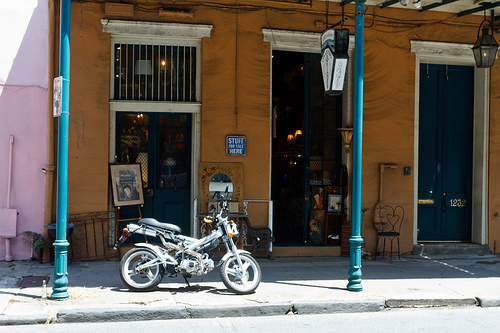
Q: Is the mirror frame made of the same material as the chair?
A: No, the frame is made of wood and the chair is made of metal.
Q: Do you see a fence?
A: No, there are no fences.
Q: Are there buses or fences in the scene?
A: No, there are no fences or buses.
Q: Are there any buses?
A: No, there are no buses.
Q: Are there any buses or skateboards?
A: No, there are no buses or skateboards.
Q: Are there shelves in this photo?
A: No, there are no shelves.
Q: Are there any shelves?
A: No, there are no shelves.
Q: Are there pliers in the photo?
A: No, there are no pliers.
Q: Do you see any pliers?
A: No, there are no pliers.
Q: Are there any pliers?
A: No, there are no pliers.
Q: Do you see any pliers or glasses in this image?
A: No, there are no pliers or glasses.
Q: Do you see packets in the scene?
A: No, there are no packets.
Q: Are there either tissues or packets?
A: No, there are no packets or tissues.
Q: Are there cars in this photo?
A: No, there are no cars.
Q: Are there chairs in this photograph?
A: Yes, there is a chair.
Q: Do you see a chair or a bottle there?
A: Yes, there is a chair.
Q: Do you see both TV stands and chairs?
A: No, there is a chair but no TV stands.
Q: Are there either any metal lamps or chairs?
A: Yes, there is a metal chair.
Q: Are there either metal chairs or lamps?
A: Yes, there is a metal chair.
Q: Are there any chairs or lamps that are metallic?
A: Yes, the chair is metallic.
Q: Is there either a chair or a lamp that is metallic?
A: Yes, the chair is metallic.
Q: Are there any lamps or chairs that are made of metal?
A: Yes, the chair is made of metal.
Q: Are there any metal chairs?
A: Yes, there is a metal chair.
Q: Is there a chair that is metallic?
A: Yes, there is a chair that is metallic.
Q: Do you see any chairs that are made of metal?
A: Yes, there is a chair that is made of metal.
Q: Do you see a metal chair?
A: Yes, there is a chair that is made of metal.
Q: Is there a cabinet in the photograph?
A: No, there are no cabinets.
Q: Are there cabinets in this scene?
A: No, there are no cabinets.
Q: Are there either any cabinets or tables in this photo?
A: No, there are no cabinets or tables.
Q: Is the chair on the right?
A: Yes, the chair is on the right of the image.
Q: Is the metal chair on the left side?
A: No, the chair is on the right of the image.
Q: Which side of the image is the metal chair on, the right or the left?
A: The chair is on the right of the image.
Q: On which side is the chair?
A: The chair is on the right of the image.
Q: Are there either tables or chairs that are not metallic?
A: No, there is a chair but it is metallic.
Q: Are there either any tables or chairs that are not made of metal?
A: No, there is a chair but it is made of metal.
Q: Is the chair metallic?
A: Yes, the chair is metallic.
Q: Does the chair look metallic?
A: Yes, the chair is metallic.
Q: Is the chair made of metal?
A: Yes, the chair is made of metal.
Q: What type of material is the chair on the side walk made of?
A: The chair is made of metal.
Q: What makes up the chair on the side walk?
A: The chair is made of metal.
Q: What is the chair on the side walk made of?
A: The chair is made of metal.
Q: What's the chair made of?
A: The chair is made of metal.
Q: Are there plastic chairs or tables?
A: No, there is a chair but it is metallic.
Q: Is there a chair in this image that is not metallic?
A: No, there is a chair but it is metallic.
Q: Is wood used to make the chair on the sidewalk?
A: No, the chair is made of metal.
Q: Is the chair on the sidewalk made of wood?
A: No, the chair is made of metal.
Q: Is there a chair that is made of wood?
A: No, there is a chair but it is made of metal.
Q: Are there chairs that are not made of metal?
A: No, there is a chair but it is made of metal.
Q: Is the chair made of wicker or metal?
A: The chair is made of metal.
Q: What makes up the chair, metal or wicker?
A: The chair is made of metal.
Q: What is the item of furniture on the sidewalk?
A: The piece of furniture is a chair.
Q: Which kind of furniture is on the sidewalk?
A: The piece of furniture is a chair.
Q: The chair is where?
A: The chair is on the side walk.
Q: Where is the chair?
A: The chair is on the side walk.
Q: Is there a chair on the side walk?
A: Yes, there is a chair on the side walk.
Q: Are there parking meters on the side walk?
A: No, there is a chair on the side walk.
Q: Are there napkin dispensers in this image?
A: No, there are no napkin dispensers.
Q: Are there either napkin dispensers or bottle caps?
A: No, there are no napkin dispensers or bottle caps.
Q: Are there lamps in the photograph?
A: Yes, there is a lamp.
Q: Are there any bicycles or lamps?
A: Yes, there is a lamp.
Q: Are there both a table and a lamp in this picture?
A: No, there is a lamp but no tables.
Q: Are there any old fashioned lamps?
A: Yes, there is an old fashioned lamp.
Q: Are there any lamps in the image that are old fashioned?
A: Yes, there is a lamp that is old fashioned.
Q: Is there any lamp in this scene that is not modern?
A: Yes, there is a old fashioned lamp.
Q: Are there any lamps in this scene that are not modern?
A: Yes, there is a old fashioned lamp.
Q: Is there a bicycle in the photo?
A: No, there are no bicycles.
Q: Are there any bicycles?
A: No, there are no bicycles.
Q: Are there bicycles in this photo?
A: No, there are no bicycles.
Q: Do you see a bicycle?
A: No, there are no bicycles.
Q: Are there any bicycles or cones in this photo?
A: No, there are no bicycles or cones.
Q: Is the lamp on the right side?
A: Yes, the lamp is on the right of the image.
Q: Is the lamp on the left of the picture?
A: No, the lamp is on the right of the image.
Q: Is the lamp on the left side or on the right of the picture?
A: The lamp is on the right of the image.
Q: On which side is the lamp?
A: The lamp is on the right of the image.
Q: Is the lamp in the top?
A: Yes, the lamp is in the top of the image.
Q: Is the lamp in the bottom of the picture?
A: No, the lamp is in the top of the image.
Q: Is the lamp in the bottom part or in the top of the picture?
A: The lamp is in the top of the image.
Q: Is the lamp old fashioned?
A: Yes, the lamp is old fashioned.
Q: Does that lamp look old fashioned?
A: Yes, the lamp is old fashioned.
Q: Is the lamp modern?
A: No, the lamp is old fashioned.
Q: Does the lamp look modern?
A: No, the lamp is old fashioned.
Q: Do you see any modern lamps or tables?
A: No, there is a lamp but it is old fashioned.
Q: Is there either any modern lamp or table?
A: No, there is a lamp but it is old fashioned.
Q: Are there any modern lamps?
A: No, there is a lamp but it is old fashioned.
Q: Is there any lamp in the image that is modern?
A: No, there is a lamp but it is old fashioned.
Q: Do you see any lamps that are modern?
A: No, there is a lamp but it is old fashioned.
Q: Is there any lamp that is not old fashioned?
A: No, there is a lamp but it is old fashioned.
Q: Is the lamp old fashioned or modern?
A: The lamp is old fashioned.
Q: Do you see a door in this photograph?
A: Yes, there is a door.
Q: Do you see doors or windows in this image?
A: Yes, there is a door.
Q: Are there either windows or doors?
A: Yes, there is a door.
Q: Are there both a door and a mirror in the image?
A: Yes, there are both a door and a mirror.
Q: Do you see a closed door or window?
A: Yes, there is a closed door.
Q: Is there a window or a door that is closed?
A: Yes, the door is closed.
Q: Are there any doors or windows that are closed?
A: Yes, the door is closed.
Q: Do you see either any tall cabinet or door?
A: Yes, there is a tall door.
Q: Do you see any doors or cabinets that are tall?
A: Yes, the door is tall.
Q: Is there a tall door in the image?
A: Yes, there is a tall door.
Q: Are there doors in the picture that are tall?
A: Yes, there is a door that is tall.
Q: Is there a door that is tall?
A: Yes, there is a door that is tall.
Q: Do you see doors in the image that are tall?
A: Yes, there is a door that is tall.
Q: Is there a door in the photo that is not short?
A: Yes, there is a tall door.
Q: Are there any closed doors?
A: Yes, there is a closed door.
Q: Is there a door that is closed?
A: Yes, there is a door that is closed.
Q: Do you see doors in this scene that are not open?
A: Yes, there is an closed door.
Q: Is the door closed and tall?
A: Yes, the door is closed and tall.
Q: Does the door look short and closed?
A: No, the door is closed but tall.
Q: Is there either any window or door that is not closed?
A: No, there is a door but it is closed.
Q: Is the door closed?
A: Yes, the door is closed.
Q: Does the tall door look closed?
A: Yes, the door is closed.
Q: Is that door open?
A: No, the door is closed.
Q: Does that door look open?
A: No, the door is closed.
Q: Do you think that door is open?
A: No, the door is closed.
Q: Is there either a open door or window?
A: No, there is a door but it is closed.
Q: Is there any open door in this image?
A: No, there is a door but it is closed.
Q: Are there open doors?
A: No, there is a door but it is closed.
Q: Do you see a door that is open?
A: No, there is a door but it is closed.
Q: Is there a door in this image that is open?
A: No, there is a door but it is closed.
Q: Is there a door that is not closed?
A: No, there is a door but it is closed.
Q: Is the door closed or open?
A: The door is closed.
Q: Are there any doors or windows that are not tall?
A: No, there is a door but it is tall.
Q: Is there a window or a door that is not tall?
A: No, there is a door but it is tall.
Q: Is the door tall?
A: Yes, the door is tall.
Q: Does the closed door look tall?
A: Yes, the door is tall.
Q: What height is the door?
A: The door is tall.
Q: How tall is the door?
A: The door is tall.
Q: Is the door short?
A: No, the door is tall.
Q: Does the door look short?
A: No, the door is tall.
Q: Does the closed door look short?
A: No, the door is tall.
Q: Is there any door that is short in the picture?
A: No, there is a door but it is tall.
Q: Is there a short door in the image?
A: No, there is a door but it is tall.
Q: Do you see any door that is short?
A: No, there is a door but it is tall.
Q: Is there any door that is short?
A: No, there is a door but it is tall.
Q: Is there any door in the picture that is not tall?
A: No, there is a door but it is tall.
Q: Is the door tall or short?
A: The door is tall.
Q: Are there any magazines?
A: No, there are no magazines.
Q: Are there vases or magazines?
A: No, there are no magazines or vases.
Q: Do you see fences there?
A: No, there are no fences.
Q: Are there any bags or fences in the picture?
A: No, there are no fences or bags.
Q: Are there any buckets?
A: No, there are no buckets.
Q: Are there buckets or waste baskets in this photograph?
A: No, there are no buckets or waste baskets.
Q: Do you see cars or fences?
A: No, there are no cars or fences.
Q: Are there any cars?
A: No, there are no cars.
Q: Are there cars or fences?
A: No, there are no cars or fences.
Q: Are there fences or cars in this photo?
A: No, there are no cars or fences.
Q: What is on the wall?
A: The sign is on the wall.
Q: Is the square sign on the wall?
A: Yes, the sign is on the wall.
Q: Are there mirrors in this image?
A: Yes, there is a mirror.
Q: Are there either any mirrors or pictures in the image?
A: Yes, there is a mirror.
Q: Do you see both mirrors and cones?
A: No, there is a mirror but no cones.